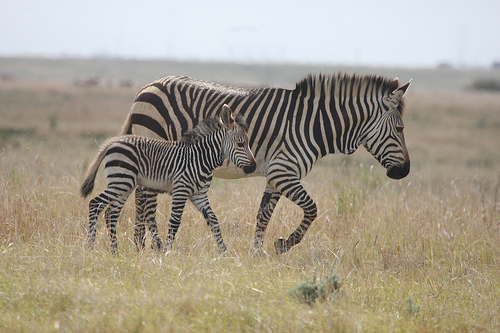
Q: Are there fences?
A: No, there are no fences.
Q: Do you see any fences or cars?
A: No, there are no fences or cars.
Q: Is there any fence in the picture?
A: No, there are no fences.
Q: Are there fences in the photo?
A: No, there are no fences.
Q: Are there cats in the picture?
A: No, there are no cats.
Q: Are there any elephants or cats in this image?
A: No, there are no cats or elephants.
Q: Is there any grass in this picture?
A: Yes, there is grass.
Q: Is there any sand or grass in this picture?
A: Yes, there is grass.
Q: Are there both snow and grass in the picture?
A: No, there is grass but no snow.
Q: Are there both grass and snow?
A: No, there is grass but no snow.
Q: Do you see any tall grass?
A: Yes, there is tall grass.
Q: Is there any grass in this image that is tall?
A: Yes, there is grass that is tall.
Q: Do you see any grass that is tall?
A: Yes, there is grass that is tall.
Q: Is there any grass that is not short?
A: Yes, there is tall grass.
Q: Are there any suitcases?
A: No, there are no suitcases.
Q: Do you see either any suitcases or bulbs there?
A: No, there are no suitcases or bulbs.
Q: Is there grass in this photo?
A: Yes, there is grass.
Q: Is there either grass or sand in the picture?
A: Yes, there is grass.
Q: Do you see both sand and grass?
A: No, there is grass but no sand.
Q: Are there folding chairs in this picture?
A: No, there are no folding chairs.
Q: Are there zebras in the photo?
A: Yes, there is a zebra.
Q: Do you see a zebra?
A: Yes, there is a zebra.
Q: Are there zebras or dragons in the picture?
A: Yes, there is a zebra.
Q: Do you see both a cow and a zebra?
A: No, there is a zebra but no cows.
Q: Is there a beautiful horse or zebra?
A: Yes, there is a beautiful zebra.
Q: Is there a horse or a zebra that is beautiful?
A: Yes, the zebra is beautiful.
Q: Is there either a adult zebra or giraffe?
A: Yes, there is an adult zebra.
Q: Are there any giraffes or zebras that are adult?
A: Yes, the zebra is adult.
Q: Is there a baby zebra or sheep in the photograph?
A: Yes, there is a baby zebra.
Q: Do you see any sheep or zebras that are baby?
A: Yes, the zebra is a baby.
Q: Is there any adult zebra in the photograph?
A: Yes, there is an adult zebra.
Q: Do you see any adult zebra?
A: Yes, there is an adult zebra.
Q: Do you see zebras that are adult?
A: Yes, there is a zebra that is adult.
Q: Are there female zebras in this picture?
A: Yes, there is a female zebra.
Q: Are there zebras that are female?
A: Yes, there is a zebra that is female.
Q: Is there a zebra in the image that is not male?
A: Yes, there is a female zebra.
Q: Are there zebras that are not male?
A: Yes, there is a female zebra.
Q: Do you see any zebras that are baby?
A: Yes, there is a baby zebra.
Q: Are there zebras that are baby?
A: Yes, there is a zebra that is a baby.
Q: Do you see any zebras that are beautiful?
A: Yes, there is a beautiful zebra.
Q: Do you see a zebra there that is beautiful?
A: Yes, there is a zebra that is beautiful.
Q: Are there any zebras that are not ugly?
A: Yes, there is an beautiful zebra.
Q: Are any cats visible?
A: No, there are no cats.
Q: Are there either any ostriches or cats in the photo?
A: No, there are no cats or ostriches.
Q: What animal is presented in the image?
A: The animal is a zebra.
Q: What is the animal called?
A: The animal is a zebra.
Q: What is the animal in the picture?
A: The animal is a zebra.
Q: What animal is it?
A: The animal is a zebra.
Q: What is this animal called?
A: This is a zebra.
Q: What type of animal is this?
A: This is a zebra.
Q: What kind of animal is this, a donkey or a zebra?
A: This is a zebra.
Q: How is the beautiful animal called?
A: The animal is a zebra.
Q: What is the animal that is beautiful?
A: The animal is a zebra.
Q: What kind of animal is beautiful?
A: The animal is a zebra.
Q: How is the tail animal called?
A: The animal is a zebra.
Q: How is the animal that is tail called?
A: The animal is a zebra.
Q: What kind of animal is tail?
A: The animal is a zebra.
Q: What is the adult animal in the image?
A: The animal is a zebra.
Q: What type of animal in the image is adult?
A: The animal is a zebra.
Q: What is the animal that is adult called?
A: The animal is a zebra.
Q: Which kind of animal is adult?
A: The animal is a zebra.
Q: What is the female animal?
A: The animal is a zebra.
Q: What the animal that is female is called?
A: The animal is a zebra.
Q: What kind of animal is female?
A: The animal is a zebra.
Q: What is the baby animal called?
A: The animal is a zebra.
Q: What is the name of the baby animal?
A: The animal is a zebra.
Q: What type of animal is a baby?
A: The animal is a zebra.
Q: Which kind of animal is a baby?
A: The animal is a zebra.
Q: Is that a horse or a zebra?
A: That is a zebra.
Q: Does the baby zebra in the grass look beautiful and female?
A: Yes, the zebra is beautiful and female.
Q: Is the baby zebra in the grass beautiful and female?
A: Yes, the zebra is beautiful and female.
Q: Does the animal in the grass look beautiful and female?
A: Yes, the zebra is beautiful and female.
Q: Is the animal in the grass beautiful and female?
A: Yes, the zebra is beautiful and female.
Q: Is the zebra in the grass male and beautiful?
A: No, the zebra is beautiful but female.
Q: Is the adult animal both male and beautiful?
A: No, the zebra is beautiful but female.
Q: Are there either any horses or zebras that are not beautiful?
A: No, there is a zebra but she is beautiful.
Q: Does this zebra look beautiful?
A: Yes, the zebra is beautiful.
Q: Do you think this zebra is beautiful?
A: Yes, the zebra is beautiful.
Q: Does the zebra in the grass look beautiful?
A: Yes, the zebra is beautiful.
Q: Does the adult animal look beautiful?
A: Yes, the zebra is beautiful.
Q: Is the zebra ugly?
A: No, the zebra is beautiful.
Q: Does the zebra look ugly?
A: No, the zebra is beautiful.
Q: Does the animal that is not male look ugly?
A: No, the zebra is beautiful.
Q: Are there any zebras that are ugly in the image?
A: No, there is a zebra but she is beautiful.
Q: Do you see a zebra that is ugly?
A: No, there is a zebra but she is beautiful.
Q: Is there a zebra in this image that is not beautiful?
A: No, there is a zebra but she is beautiful.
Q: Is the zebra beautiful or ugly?
A: The zebra is beautiful.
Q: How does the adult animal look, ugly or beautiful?
A: The zebra is beautiful.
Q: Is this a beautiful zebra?
A: Yes, this is a beautiful zebra.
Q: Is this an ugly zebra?
A: No, this is a beautiful zebra.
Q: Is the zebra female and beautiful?
A: Yes, the zebra is female and beautiful.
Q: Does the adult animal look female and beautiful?
A: Yes, the zebra is female and beautiful.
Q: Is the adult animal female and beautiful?
A: Yes, the zebra is female and beautiful.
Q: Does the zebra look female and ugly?
A: No, the zebra is female but beautiful.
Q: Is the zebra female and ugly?
A: No, the zebra is female but beautiful.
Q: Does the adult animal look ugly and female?
A: No, the zebra is female but beautiful.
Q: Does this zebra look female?
A: Yes, the zebra is female.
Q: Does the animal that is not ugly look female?
A: Yes, the zebra is female.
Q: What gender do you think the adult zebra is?
A: The zebra is female.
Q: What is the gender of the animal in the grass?
A: The zebra is female.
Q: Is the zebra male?
A: No, the zebra is female.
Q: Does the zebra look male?
A: No, the zebra is female.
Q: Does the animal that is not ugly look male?
A: No, the zebra is female.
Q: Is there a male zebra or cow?
A: No, there is a zebra but she is female.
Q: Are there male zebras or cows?
A: No, there is a zebra but she is female.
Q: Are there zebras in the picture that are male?
A: No, there is a zebra but she is female.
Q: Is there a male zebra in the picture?
A: No, there is a zebra but she is female.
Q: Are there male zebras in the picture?
A: No, there is a zebra but she is female.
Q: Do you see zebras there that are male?
A: No, there is a zebra but she is female.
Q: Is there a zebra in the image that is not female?
A: No, there is a zebra but she is female.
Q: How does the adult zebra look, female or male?
A: The zebra is female.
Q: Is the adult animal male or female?
A: The zebra is female.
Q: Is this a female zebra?
A: Yes, this is a female zebra.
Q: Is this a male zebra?
A: No, this is a female zebra.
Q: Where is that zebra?
A: The zebra is in the grass.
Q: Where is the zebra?
A: The zebra is in the grass.